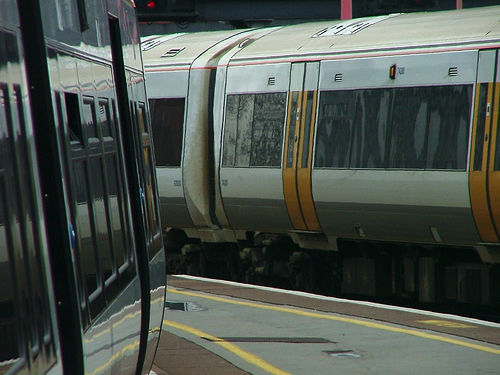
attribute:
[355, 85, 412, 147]
window — glass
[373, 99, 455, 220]
window — glass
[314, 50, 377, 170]
window — glass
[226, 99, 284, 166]
window — glass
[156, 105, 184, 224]
window — glass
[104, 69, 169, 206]
window — glass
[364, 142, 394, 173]
car — grey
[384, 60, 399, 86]
light — yellow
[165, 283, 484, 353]
line — yellow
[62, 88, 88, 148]
window — small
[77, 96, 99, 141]
window — small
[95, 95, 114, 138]
window — small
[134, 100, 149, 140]
window — small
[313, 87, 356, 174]
window — small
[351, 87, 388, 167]
window — small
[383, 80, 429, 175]
window — small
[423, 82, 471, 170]
window — small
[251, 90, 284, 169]
window — small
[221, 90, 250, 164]
window — small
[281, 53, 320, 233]
doors — long, yellow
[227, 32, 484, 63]
stripes — blue, red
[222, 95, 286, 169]
window — black, dirty